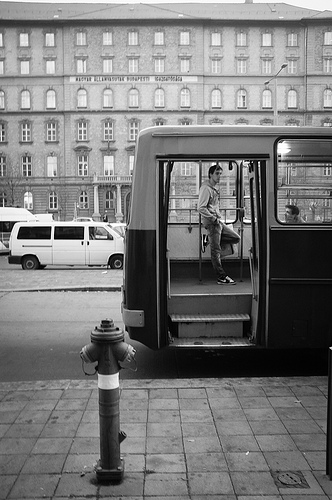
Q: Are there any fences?
A: No, there are no fences.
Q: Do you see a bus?
A: Yes, there is a bus.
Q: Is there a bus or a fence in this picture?
A: Yes, there is a bus.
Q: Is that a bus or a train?
A: That is a bus.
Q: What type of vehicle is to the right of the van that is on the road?
A: The vehicle is a bus.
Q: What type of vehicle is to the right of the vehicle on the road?
A: The vehicle is a bus.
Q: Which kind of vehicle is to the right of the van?
A: The vehicle is a bus.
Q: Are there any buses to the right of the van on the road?
A: Yes, there is a bus to the right of the van.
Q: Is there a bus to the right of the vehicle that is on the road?
A: Yes, there is a bus to the right of the van.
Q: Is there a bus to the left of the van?
A: No, the bus is to the right of the van.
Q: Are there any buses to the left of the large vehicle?
A: No, the bus is to the right of the van.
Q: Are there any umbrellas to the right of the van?
A: No, there is a bus to the right of the van.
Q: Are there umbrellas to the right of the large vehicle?
A: No, there is a bus to the right of the van.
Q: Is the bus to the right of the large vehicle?
A: Yes, the bus is to the right of the van.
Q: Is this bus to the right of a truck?
A: No, the bus is to the right of the van.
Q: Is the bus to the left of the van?
A: No, the bus is to the right of the van.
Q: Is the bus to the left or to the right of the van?
A: The bus is to the right of the van.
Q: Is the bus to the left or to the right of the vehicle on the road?
A: The bus is to the right of the van.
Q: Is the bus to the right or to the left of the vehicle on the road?
A: The bus is to the right of the van.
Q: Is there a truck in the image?
A: No, there are no trucks.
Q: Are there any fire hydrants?
A: Yes, there is a fire hydrant.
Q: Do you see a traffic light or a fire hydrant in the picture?
A: Yes, there is a fire hydrant.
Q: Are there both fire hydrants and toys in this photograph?
A: No, there is a fire hydrant but no toys.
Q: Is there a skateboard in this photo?
A: No, there are no skateboards.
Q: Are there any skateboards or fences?
A: No, there are no skateboards or fences.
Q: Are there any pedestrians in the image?
A: No, there are no pedestrians.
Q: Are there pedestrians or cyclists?
A: No, there are no pedestrians or cyclists.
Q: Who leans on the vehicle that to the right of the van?
A: The man leans on the bus.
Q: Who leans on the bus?
A: The man leans on the bus.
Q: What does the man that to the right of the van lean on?
A: The man leans on the bus.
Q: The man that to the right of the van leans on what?
A: The man leans on the bus.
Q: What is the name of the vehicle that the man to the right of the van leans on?
A: The vehicle is a bus.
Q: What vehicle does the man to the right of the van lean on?
A: The man leans on the bus.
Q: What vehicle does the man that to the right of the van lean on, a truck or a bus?
A: The man leans on a bus.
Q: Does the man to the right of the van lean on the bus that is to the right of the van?
A: Yes, the man leans on the bus.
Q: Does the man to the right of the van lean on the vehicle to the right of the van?
A: Yes, the man leans on the bus.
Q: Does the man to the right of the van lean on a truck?
A: No, the man leans on the bus.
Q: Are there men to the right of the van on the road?
A: Yes, there is a man to the right of the van.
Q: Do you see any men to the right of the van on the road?
A: Yes, there is a man to the right of the van.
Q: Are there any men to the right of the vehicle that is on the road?
A: Yes, there is a man to the right of the van.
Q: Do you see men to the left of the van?
A: No, the man is to the right of the van.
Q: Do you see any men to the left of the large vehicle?
A: No, the man is to the right of the van.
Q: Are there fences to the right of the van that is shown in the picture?
A: No, there is a man to the right of the van.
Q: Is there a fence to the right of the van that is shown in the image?
A: No, there is a man to the right of the van.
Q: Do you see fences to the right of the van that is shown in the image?
A: No, there is a man to the right of the van.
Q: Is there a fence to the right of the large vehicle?
A: No, there is a man to the right of the van.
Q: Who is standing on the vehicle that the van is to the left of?
A: The man is standing on the bus.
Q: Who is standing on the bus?
A: The man is standing on the bus.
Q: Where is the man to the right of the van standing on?
A: The man is standing on the bus.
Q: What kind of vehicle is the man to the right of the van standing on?
A: The man is standing on the bus.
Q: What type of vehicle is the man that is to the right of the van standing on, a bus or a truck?
A: The man is standing on a bus.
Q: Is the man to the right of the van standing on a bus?
A: Yes, the man is standing on a bus.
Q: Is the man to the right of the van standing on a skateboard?
A: No, the man is standing on a bus.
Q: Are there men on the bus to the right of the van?
A: Yes, there is a man on the bus.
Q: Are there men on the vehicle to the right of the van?
A: Yes, there is a man on the bus.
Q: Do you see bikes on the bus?
A: No, there is a man on the bus.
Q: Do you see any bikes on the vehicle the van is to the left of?
A: No, there is a man on the bus.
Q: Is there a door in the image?
A: Yes, there is a door.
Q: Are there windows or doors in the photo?
A: Yes, there is a door.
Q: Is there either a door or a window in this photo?
A: Yes, there is a door.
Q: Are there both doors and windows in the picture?
A: Yes, there are both a door and a window.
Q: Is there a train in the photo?
A: No, there are no trains.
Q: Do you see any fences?
A: No, there are no fences.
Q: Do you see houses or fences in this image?
A: No, there are no fences or houses.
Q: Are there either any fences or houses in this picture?
A: No, there are no fences or houses.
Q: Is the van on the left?
A: Yes, the van is on the left of the image.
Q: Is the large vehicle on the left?
A: Yes, the van is on the left of the image.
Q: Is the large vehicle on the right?
A: No, the van is on the left of the image.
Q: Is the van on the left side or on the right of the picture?
A: The van is on the left of the image.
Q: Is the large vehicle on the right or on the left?
A: The van is on the left of the image.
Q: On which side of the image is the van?
A: The van is on the left of the image.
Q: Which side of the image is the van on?
A: The van is on the left of the image.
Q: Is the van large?
A: Yes, the van is large.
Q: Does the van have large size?
A: Yes, the van is large.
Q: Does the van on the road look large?
A: Yes, the van is large.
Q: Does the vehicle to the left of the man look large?
A: Yes, the van is large.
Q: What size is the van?
A: The van is large.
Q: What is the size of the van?
A: The van is large.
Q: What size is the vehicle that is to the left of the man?
A: The van is large.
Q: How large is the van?
A: The van is large.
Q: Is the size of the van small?
A: No, the van is large.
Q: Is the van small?
A: No, the van is large.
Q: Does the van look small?
A: No, the van is large.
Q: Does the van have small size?
A: No, the van is large.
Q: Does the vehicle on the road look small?
A: No, the van is large.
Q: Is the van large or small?
A: The van is large.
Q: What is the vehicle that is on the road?
A: The vehicle is a van.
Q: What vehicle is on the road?
A: The vehicle is a van.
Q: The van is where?
A: The van is on the road.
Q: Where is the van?
A: The van is on the road.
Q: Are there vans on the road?
A: Yes, there is a van on the road.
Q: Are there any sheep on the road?
A: No, there is a van on the road.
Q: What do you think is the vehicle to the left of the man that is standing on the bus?
A: The vehicle is a van.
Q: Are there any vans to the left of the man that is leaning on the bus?
A: Yes, there is a van to the left of the man.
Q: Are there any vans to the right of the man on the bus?
A: No, the van is to the left of the man.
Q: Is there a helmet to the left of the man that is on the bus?
A: No, there is a van to the left of the man.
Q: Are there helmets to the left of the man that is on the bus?
A: No, there is a van to the left of the man.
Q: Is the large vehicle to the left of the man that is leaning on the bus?
A: Yes, the van is to the left of the man.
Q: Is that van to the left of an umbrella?
A: No, the van is to the left of the man.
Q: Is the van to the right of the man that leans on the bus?
A: No, the van is to the left of the man.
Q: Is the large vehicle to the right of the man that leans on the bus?
A: No, the van is to the left of the man.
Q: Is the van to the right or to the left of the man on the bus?
A: The van is to the left of the man.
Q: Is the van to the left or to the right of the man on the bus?
A: The van is to the left of the man.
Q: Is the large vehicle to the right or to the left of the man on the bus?
A: The van is to the left of the man.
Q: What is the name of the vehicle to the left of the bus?
A: The vehicle is a van.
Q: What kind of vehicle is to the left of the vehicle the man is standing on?
A: The vehicle is a van.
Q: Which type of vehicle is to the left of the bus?
A: The vehicle is a van.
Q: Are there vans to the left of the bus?
A: Yes, there is a van to the left of the bus.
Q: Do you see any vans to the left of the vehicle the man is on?
A: Yes, there is a van to the left of the bus.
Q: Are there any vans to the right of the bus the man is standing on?
A: No, the van is to the left of the bus.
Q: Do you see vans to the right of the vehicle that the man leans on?
A: No, the van is to the left of the bus.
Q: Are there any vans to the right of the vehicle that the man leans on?
A: No, the van is to the left of the bus.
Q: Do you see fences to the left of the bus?
A: No, there is a van to the left of the bus.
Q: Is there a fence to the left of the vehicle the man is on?
A: No, there is a van to the left of the bus.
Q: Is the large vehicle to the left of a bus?
A: Yes, the van is to the left of a bus.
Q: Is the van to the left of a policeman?
A: No, the van is to the left of a bus.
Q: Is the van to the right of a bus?
A: No, the van is to the left of a bus.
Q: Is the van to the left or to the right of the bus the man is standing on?
A: The van is to the left of the bus.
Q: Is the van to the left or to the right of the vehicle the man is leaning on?
A: The van is to the left of the bus.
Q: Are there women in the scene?
A: No, there are no women.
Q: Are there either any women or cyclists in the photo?
A: No, there are no women or cyclists.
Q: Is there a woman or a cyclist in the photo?
A: No, there are no women or cyclists.